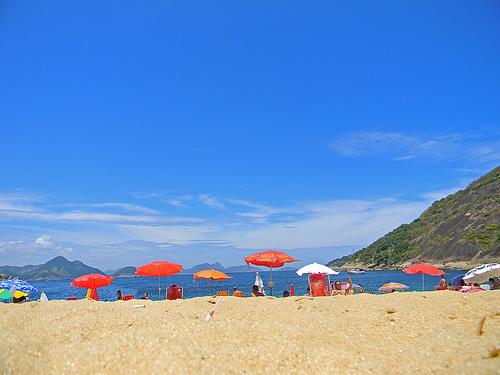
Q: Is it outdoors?
A: Yes, it is outdoors.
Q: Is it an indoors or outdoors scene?
A: It is outdoors.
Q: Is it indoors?
A: No, it is outdoors.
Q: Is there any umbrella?
A: Yes, there is an umbrella.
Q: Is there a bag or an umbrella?
A: Yes, there is an umbrella.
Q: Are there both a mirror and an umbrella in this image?
A: No, there is an umbrella but no mirrors.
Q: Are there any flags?
A: No, there are no flags.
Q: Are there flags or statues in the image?
A: No, there are no flags or statues.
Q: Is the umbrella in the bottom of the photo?
A: Yes, the umbrella is in the bottom of the image.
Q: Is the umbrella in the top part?
A: No, the umbrella is in the bottom of the image.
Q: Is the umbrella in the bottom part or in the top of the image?
A: The umbrella is in the bottom of the image.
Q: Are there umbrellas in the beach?
A: Yes, there is an umbrella in the beach.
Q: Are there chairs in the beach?
A: No, there is an umbrella in the beach.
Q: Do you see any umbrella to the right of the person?
A: Yes, there is an umbrella to the right of the person.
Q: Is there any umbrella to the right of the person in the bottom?
A: Yes, there is an umbrella to the right of the person.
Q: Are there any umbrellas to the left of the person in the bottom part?
A: No, the umbrella is to the right of the person.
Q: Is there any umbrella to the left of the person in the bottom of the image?
A: No, the umbrella is to the right of the person.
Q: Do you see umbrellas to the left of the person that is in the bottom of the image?
A: No, the umbrella is to the right of the person.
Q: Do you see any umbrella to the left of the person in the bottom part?
A: No, the umbrella is to the right of the person.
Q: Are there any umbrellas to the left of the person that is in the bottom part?
A: No, the umbrella is to the right of the person.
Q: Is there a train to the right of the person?
A: No, there is an umbrella to the right of the person.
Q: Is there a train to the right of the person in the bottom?
A: No, there is an umbrella to the right of the person.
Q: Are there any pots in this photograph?
A: No, there are no pots.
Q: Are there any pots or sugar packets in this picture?
A: No, there are no pots or sugar packets.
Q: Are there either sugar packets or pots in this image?
A: No, there are no pots or sugar packets.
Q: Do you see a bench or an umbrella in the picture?
A: Yes, there is an umbrella.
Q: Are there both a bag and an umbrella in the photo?
A: No, there is an umbrella but no bags.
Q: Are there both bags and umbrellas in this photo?
A: No, there is an umbrella but no bags.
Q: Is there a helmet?
A: No, there are no helmets.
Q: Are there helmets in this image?
A: No, there are no helmets.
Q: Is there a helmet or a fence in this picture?
A: No, there are no helmets or fences.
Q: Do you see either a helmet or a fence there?
A: No, there are no helmets or fences.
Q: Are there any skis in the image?
A: No, there are no skis.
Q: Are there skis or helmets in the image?
A: No, there are no skis or helmets.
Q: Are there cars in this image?
A: No, there are no cars.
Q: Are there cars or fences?
A: No, there are no cars or fences.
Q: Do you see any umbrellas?
A: Yes, there is an umbrella.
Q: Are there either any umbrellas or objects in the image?
A: Yes, there is an umbrella.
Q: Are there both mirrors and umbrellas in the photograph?
A: No, there is an umbrella but no mirrors.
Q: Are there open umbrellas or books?
A: Yes, there is an open umbrella.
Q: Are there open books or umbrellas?
A: Yes, there is an open umbrella.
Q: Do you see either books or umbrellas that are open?
A: Yes, the umbrella is open.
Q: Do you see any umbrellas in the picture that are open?
A: Yes, there is an open umbrella.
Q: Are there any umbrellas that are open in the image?
A: Yes, there is an open umbrella.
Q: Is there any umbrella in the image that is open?
A: Yes, there is an umbrella that is open.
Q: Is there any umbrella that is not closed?
A: Yes, there is a open umbrella.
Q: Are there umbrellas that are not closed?
A: Yes, there is a open umbrella.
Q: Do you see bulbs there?
A: No, there are no bulbs.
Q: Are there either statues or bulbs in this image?
A: No, there are no bulbs or statues.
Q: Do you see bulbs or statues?
A: No, there are no bulbs or statues.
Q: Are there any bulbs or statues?
A: No, there are no bulbs or statues.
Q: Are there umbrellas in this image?
A: Yes, there is an umbrella.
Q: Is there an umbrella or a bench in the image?
A: Yes, there is an umbrella.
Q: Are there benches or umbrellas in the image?
A: Yes, there is an umbrella.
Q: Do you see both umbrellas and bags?
A: No, there is an umbrella but no bags.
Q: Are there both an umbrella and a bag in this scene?
A: No, there is an umbrella but no bags.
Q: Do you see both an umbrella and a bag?
A: No, there is an umbrella but no bags.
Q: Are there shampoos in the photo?
A: No, there are no shampoos.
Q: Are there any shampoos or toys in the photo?
A: No, there are no shampoos or toys.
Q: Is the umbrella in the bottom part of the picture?
A: Yes, the umbrella is in the bottom of the image.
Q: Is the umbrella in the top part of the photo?
A: No, the umbrella is in the bottom of the image.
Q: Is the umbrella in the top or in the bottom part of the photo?
A: The umbrella is in the bottom of the image.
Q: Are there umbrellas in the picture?
A: Yes, there is an umbrella.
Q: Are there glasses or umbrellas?
A: Yes, there is an umbrella.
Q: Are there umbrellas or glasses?
A: Yes, there is an umbrella.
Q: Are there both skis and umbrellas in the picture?
A: No, there is an umbrella but no skis.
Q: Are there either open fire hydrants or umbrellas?
A: Yes, there is an open umbrella.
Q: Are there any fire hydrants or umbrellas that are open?
A: Yes, the umbrella is open.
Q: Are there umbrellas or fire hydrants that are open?
A: Yes, the umbrella is open.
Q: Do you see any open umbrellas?
A: Yes, there is an open umbrella.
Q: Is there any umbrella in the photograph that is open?
A: Yes, there is an umbrella that is open.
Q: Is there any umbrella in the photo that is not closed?
A: Yes, there is a open umbrella.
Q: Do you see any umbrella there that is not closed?
A: Yes, there is a open umbrella.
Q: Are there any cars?
A: No, there are no cars.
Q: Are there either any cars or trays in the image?
A: No, there are no cars or trays.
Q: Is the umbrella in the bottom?
A: Yes, the umbrella is in the bottom of the image.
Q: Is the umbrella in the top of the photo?
A: No, the umbrella is in the bottom of the image.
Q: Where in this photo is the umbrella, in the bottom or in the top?
A: The umbrella is in the bottom of the image.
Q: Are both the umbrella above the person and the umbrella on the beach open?
A: Yes, both the umbrella and the umbrella are open.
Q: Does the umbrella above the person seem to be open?
A: Yes, the umbrella is open.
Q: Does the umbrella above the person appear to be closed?
A: No, the umbrella is open.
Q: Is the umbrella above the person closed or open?
A: The umbrella is open.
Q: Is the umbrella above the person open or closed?
A: The umbrella is open.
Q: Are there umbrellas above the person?
A: Yes, there is an umbrella above the person.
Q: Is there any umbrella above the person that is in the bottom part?
A: Yes, there is an umbrella above the person.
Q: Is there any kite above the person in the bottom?
A: No, there is an umbrella above the person.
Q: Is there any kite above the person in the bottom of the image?
A: No, there is an umbrella above the person.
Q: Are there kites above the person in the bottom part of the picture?
A: No, there is an umbrella above the person.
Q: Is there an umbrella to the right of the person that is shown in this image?
A: Yes, there is an umbrella to the right of the person.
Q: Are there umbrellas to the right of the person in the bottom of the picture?
A: Yes, there is an umbrella to the right of the person.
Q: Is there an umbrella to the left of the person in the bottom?
A: No, the umbrella is to the right of the person.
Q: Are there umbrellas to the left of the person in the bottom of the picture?
A: No, the umbrella is to the right of the person.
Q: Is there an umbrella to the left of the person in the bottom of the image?
A: No, the umbrella is to the right of the person.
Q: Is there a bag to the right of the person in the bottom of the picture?
A: No, there is an umbrella to the right of the person.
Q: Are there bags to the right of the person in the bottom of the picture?
A: No, there is an umbrella to the right of the person.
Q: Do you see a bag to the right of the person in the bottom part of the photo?
A: No, there is an umbrella to the right of the person.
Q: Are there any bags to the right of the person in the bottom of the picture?
A: No, there is an umbrella to the right of the person.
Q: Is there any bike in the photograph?
A: No, there are no bikes.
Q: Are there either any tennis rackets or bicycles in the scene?
A: No, there are no bicycles or tennis rackets.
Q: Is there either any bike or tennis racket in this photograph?
A: No, there are no bikes or rackets.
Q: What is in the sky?
A: The clouds are in the sky.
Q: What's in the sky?
A: The clouds are in the sky.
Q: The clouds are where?
A: The clouds are in the sky.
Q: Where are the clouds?
A: The clouds are in the sky.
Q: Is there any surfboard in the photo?
A: No, there are no surfboards.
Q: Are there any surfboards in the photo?
A: No, there are no surfboards.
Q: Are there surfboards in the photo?
A: No, there are no surfboards.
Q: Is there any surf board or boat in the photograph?
A: No, there are no surfboards or boats.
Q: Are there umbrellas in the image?
A: Yes, there is an umbrella.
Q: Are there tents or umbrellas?
A: Yes, there is an umbrella.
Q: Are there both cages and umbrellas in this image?
A: No, there is an umbrella but no cages.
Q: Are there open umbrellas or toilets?
A: Yes, there is an open umbrella.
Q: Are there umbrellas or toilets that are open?
A: Yes, the umbrella is open.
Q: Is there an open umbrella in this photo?
A: Yes, there is an open umbrella.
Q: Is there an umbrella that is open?
A: Yes, there is an umbrella that is open.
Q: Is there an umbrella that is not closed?
A: Yes, there is a open umbrella.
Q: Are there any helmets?
A: No, there are no helmets.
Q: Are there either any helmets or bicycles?
A: No, there are no helmets or bicycles.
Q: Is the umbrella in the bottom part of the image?
A: Yes, the umbrella is in the bottom of the image.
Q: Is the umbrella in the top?
A: No, the umbrella is in the bottom of the image.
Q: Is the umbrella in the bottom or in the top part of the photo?
A: The umbrella is in the bottom of the image.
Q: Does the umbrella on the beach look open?
A: Yes, the umbrella is open.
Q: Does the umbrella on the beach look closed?
A: No, the umbrella is open.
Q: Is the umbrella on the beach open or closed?
A: The umbrella is open.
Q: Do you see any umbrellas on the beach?
A: Yes, there is an umbrella on the beach.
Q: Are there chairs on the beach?
A: No, there is an umbrella on the beach.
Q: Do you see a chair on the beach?
A: No, there is an umbrella on the beach.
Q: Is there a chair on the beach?
A: No, there is an umbrella on the beach.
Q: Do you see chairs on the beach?
A: No, there is an umbrella on the beach.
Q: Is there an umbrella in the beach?
A: Yes, there is an umbrella in the beach.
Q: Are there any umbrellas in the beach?
A: Yes, there is an umbrella in the beach.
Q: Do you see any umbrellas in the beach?
A: Yes, there is an umbrella in the beach.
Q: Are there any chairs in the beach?
A: No, there is an umbrella in the beach.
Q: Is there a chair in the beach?
A: No, there is an umbrella in the beach.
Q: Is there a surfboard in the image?
A: No, there are no surfboards.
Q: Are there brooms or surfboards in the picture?
A: No, there are no surfboards or brooms.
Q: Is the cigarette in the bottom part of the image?
A: Yes, the cigarette is in the bottom of the image.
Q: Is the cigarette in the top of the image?
A: No, the cigarette is in the bottom of the image.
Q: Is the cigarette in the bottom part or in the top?
A: The cigarette is in the bottom of the image.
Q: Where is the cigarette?
A: The cigarette is on the beach.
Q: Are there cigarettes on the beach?
A: Yes, there is a cigarette on the beach.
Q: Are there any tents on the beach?
A: No, there is a cigarette on the beach.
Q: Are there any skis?
A: No, there are no skis.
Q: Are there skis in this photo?
A: No, there are no skis.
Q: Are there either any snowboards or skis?
A: No, there are no skis or snowboards.